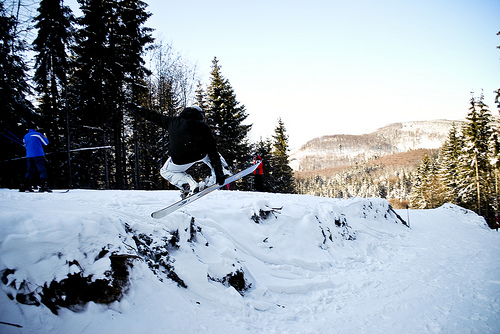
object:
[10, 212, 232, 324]
rock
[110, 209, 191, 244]
snow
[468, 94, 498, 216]
trees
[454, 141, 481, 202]
snow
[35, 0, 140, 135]
trees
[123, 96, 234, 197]
man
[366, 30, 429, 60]
white clouds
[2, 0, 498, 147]
blue sky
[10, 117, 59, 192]
person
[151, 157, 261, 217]
snow board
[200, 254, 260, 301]
snow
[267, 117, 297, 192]
evergreen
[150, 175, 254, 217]
snowboarding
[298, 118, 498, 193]
mountain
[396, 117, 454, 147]
snow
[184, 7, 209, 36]
clouds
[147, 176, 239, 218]
board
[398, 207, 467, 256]
snow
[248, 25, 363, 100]
clouds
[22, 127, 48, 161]
jacket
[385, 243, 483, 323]
snow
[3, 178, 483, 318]
ground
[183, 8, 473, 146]
cloud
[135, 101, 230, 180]
sweater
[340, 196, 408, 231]
rock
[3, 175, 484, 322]
slope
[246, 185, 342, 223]
hill